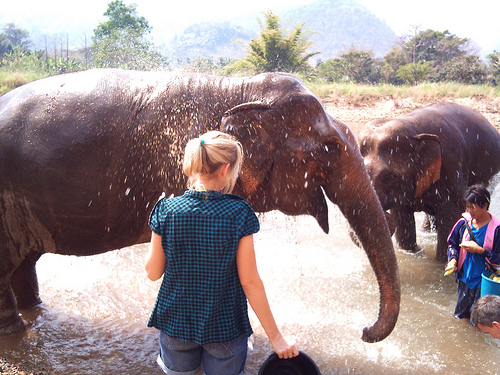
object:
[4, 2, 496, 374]
picture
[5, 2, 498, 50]
sun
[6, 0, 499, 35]
sky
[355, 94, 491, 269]
elephant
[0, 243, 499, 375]
water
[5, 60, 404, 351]
elephant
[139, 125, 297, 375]
woman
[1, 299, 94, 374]
splashes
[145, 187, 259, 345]
shirt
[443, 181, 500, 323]
lady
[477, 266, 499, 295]
bucket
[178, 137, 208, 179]
ponytail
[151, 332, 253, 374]
shorts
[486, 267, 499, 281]
sponges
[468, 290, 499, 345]
man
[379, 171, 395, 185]
eye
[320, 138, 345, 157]
eye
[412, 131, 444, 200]
ear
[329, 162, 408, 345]
trunk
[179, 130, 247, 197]
head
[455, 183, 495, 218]
head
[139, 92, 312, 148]
water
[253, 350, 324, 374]
bucket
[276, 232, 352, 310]
light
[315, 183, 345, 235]
mouth open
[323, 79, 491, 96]
grass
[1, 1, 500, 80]
vegetation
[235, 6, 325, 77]
tree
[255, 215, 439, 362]
pond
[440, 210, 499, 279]
jacket